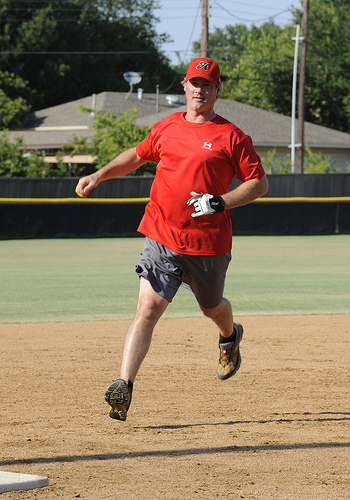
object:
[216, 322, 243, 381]
shoe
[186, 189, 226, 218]
glove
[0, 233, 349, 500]
ground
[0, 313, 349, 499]
dirt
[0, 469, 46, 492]
baseball base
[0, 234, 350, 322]
grass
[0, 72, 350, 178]
house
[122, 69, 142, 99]
antenna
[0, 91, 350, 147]
roof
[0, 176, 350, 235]
fence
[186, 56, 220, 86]
cap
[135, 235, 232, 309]
shorts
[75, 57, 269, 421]
man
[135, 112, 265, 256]
shirt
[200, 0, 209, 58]
pole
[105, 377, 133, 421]
foot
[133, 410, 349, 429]
shadow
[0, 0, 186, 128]
tree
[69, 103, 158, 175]
tree